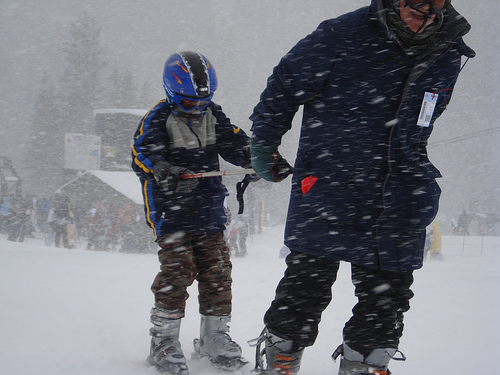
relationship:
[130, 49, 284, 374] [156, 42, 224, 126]
boy wearing helmet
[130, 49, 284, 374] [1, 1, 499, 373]
boy in snow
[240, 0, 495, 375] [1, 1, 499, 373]
man in snow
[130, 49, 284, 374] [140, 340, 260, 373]
boy wearing skis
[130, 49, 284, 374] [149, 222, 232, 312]
boy wearing pants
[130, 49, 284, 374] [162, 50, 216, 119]
boy wearing helmet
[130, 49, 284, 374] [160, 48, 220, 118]
boy wearing helmet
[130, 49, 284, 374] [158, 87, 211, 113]
boy wearing goggles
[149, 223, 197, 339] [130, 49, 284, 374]
leg of boy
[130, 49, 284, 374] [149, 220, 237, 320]
boy wearing pants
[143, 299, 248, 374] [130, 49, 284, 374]
feet of boy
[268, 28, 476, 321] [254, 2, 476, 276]
man wearing jacket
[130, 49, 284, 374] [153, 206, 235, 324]
boy wearing pants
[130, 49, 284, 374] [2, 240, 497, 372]
boy on field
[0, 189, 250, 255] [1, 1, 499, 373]
people on snow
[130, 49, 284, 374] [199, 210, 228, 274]
boy wearing cloth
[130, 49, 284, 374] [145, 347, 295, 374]
boy in snow ski's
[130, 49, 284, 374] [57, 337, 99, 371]
boy on snow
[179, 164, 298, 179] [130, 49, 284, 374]
ski pole carried by boy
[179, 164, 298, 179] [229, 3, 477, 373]
ski pole carried by man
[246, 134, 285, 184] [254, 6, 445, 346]
glove on man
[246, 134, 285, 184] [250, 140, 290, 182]
glove on hand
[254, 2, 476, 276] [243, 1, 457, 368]
jacket on man